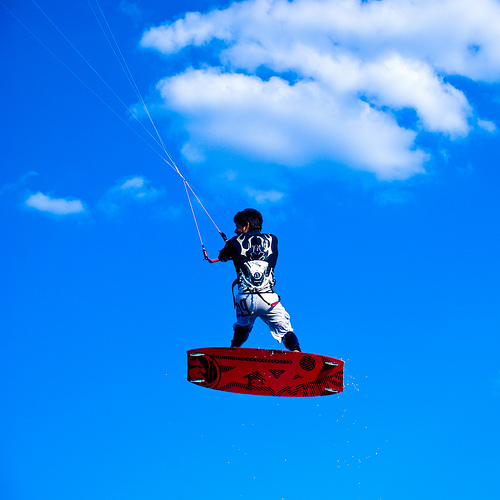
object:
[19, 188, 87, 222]
cloud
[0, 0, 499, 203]
sky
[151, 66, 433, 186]
cloud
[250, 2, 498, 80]
cloud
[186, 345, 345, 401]
windboard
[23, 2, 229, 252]
string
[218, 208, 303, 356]
man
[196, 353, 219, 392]
design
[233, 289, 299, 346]
pants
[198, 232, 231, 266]
rod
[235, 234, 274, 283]
design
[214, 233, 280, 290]
shirt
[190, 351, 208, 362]
fin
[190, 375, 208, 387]
fin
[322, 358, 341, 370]
fin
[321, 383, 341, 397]
fin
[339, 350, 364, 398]
water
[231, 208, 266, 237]
head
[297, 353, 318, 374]
circle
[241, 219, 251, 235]
ear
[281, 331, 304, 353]
boot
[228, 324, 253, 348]
boot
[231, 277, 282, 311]
suspender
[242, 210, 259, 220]
hair